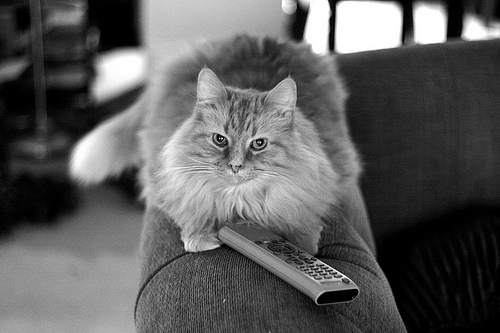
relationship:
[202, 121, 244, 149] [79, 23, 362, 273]
eye of cat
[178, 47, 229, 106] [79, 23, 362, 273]
ear of cat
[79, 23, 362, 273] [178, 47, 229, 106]
cat has ear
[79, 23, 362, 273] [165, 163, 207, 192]
cat has whiskers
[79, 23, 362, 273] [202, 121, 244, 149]
cat has eye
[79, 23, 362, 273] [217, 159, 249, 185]
cat has nose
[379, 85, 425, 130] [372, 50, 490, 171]
part of sofa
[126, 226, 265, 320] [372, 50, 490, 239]
arm of sofa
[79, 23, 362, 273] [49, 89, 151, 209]
cat has tail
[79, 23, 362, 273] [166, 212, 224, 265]
cat has paw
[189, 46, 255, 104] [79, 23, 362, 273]
fur of cat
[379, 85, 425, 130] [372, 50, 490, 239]
part of sofa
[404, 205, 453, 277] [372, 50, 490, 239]
cush of sofa